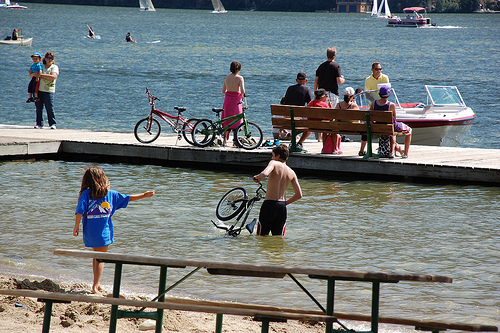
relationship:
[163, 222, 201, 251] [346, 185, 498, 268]
ripples in water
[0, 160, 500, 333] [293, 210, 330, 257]
ripples in water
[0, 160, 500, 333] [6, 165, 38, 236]
ripples in water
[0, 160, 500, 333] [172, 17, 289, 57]
ripples in water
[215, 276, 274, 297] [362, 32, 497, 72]
ripples in water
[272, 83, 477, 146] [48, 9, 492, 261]
boat in water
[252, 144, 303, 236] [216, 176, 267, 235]
boy holding bike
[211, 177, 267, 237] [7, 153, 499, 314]
bike in water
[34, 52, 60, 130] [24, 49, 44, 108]
people with boy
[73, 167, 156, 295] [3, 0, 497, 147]
girl by water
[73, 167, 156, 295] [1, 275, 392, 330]
girl on sand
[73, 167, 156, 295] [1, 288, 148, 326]
girl on sand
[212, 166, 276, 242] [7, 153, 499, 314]
bike in water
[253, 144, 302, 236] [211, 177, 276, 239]
boy in water with bike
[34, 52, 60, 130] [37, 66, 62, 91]
people wearing shirt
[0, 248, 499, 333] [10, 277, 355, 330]
picnic table in sand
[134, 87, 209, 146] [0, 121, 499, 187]
bike on dock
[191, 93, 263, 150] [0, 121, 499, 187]
bike on dock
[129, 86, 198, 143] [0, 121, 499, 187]
bike on dock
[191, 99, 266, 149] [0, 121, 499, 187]
bike on dock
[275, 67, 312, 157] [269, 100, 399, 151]
people are on bench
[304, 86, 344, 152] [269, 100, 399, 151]
people are on bench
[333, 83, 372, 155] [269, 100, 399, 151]
people are on bench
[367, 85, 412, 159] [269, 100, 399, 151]
people are on bench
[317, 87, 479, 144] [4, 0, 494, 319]
boat on water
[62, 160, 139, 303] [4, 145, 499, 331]
girl in water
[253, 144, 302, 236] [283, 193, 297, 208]
boy has hand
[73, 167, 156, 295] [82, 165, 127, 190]
girl has hairs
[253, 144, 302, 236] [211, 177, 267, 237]
boy has bike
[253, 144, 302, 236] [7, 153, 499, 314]
boy in water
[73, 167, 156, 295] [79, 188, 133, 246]
girl wearing shirt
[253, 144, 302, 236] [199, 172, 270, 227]
boy has bicycle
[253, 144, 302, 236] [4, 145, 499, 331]
boy in water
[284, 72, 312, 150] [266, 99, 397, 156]
people sitting on bench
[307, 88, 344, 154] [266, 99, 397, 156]
people sitting on bench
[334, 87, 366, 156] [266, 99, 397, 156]
people sitting on bench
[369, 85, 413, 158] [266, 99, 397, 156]
people sitting on bench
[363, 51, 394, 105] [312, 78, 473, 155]
man driving boat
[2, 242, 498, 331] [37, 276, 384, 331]
picnic table has legs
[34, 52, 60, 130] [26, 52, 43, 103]
people carrying boy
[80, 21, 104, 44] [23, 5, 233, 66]
people kayaking in water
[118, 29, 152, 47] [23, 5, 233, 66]
people kayaking in water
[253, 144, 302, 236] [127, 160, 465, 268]
boy in water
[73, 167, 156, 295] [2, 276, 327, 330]
girl in sand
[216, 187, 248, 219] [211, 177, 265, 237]
wheeel of cycle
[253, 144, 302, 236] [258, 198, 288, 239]
boy wearing pants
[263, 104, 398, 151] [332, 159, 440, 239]
bench near water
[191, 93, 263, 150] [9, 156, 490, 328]
bike near water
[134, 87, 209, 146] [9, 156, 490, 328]
bike near water